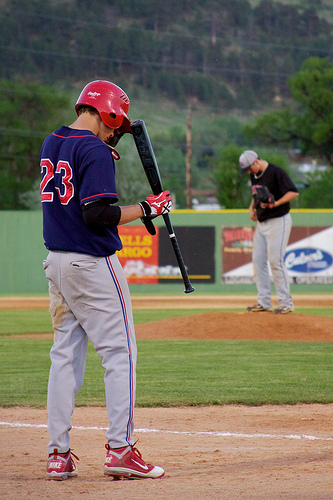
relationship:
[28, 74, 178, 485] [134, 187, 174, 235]
player wearing glove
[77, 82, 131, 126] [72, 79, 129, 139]
helmet on top of head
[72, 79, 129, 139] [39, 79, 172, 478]
head of player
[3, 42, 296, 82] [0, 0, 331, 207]
metal wire in air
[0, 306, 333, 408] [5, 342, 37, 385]
grass in field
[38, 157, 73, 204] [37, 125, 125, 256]
number on uniform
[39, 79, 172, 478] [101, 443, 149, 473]
player wearing cleats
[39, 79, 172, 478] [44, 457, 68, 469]
player wearing cleats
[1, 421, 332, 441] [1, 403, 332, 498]
line on ground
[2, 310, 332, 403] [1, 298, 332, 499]
grass on ground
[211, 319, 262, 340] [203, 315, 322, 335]
dirt on mound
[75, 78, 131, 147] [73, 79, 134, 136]
helmet red helmet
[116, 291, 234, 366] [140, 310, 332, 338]
part of a pitchers mound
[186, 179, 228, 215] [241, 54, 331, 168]
part of a tree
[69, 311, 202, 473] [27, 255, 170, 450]
gray uniform pants